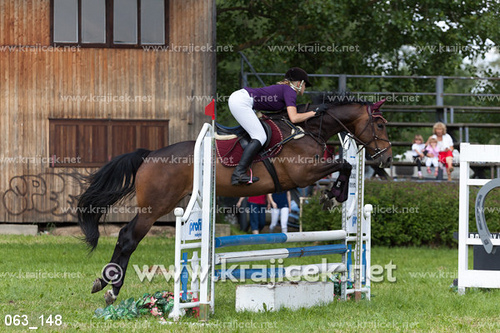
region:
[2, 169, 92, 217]
Graffiti on a building.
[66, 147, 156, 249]
A tail on a horse.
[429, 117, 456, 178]
A woman sitting down.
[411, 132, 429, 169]
A child sitting down.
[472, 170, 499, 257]
A horse shoe on a fence.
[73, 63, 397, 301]
A person riding a horse.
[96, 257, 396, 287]
A website logo across the picture.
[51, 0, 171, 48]
A window on a building.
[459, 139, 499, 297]
A white fence in the grass.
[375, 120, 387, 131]
The eye on a horse.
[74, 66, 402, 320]
a horse is jumping at a competition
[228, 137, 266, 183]
the girl has black riding boots on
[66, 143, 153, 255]
the horses tail is black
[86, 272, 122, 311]
the horses hooves are in the air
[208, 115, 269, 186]
an english riding saddle is on the horse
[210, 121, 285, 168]
the horse blanket is maroon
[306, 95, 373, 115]
the horse's mane is black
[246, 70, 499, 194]
spectators are in the stands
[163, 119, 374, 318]
the jump has blue and white rails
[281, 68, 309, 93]
a black helmet is on the rider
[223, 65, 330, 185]
Woman riding a horse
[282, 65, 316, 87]
Helmet on the woman's head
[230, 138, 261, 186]
Boot on the woman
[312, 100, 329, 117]
Glove on the woman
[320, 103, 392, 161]
Rein on the horse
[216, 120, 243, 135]
Bridge piece on the horse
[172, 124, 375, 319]
Obstacle the horse is jumping over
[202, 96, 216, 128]
Flap on the obstacle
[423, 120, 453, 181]
Woman sitting on a bench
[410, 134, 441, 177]
Kids sitting on a bench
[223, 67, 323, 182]
woman riding brown horse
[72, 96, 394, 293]
brown horse with black mane and tail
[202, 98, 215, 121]
red flag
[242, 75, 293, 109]
purple shirt of horse rider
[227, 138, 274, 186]
black boot of horse rider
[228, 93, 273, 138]
white pants of horse rider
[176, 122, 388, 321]
rail horse is jumping over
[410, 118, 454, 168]
three people watching the horse jumping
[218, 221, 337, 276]
blue and white poles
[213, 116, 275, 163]
red saddle on brown horse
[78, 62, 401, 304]
a woman riding a horse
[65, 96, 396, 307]
a horse about to jump in the air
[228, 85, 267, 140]
woman wearing tight white pants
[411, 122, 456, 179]
a woman and two kids sitting in the bleachers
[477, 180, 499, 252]
half a horse shoe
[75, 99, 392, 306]
a brown and black horse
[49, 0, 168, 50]
black window on a house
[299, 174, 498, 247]
a green edge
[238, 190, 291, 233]
two people walking toward a horse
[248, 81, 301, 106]
woman wearing a purple shirt